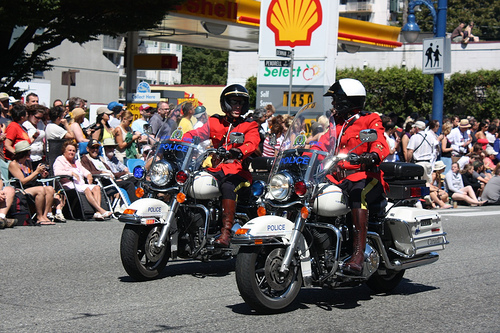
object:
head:
[219, 84, 250, 120]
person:
[169, 83, 264, 250]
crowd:
[0, 90, 208, 229]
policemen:
[301, 78, 392, 277]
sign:
[265, 0, 323, 48]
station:
[0, 0, 500, 127]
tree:
[0, 0, 189, 101]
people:
[382, 114, 500, 208]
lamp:
[397, 0, 449, 138]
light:
[400, 23, 423, 46]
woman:
[53, 140, 113, 221]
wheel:
[119, 221, 171, 282]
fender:
[118, 197, 172, 226]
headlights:
[132, 163, 191, 188]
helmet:
[219, 83, 249, 113]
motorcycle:
[231, 128, 450, 315]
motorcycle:
[117, 131, 280, 282]